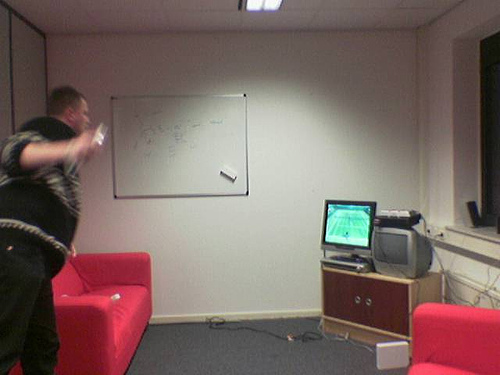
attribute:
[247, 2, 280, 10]
light — overhead, fluorescent, on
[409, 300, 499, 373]
chair — pink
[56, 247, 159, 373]
couch — pink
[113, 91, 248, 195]
board — dry erase, dry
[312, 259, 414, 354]
cabinet — wood